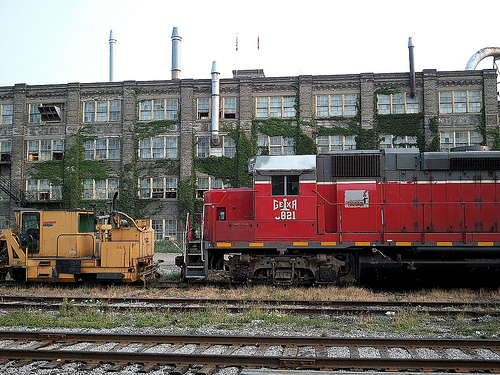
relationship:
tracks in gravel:
[1, 289, 497, 331] [0, 333, 498, 373]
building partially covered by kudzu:
[2, 65, 499, 252] [29, 114, 499, 229]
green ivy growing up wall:
[26, 85, 500, 228] [0, 78, 498, 252]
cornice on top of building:
[2, 72, 485, 101] [2, 65, 499, 252]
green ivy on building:
[23, 85, 498, 228] [2, 65, 499, 252]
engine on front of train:
[202, 187, 252, 235] [203, 149, 499, 291]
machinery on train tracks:
[3, 195, 167, 291] [6, 287, 498, 373]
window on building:
[222, 98, 235, 120] [2, 65, 499, 252]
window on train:
[271, 175, 285, 196] [174, 149, 494, 292]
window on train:
[285, 172, 298, 197] [174, 149, 494, 292]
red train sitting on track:
[175, 147, 499, 287] [1, 295, 498, 314]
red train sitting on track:
[175, 147, 499, 287] [3, 329, 498, 373]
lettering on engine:
[268, 201, 300, 224] [180, 156, 347, 288]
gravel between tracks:
[1, 296, 485, 373] [145, 325, 333, 371]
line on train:
[215, 241, 494, 246] [203, 149, 499, 291]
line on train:
[391, 240, 411, 248] [203, 149, 499, 291]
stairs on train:
[175, 198, 220, 291] [174, 149, 494, 292]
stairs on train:
[175, 198, 220, 291] [0, 193, 170, 292]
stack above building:
[172, 27, 181, 81] [1, 72, 496, 283]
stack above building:
[109, 27, 117, 82] [1, 72, 496, 283]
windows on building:
[136, 178, 181, 198] [1, 72, 496, 283]